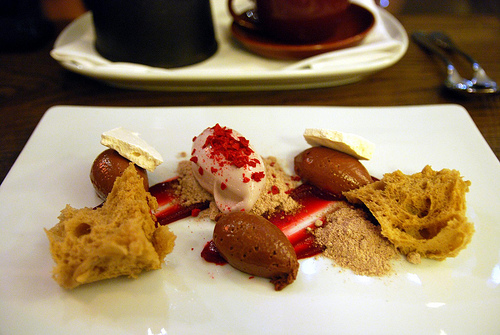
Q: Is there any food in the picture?
A: Yes, there is food.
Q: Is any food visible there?
A: Yes, there is food.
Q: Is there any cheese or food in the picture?
A: Yes, there is food.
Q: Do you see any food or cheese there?
A: Yes, there is food.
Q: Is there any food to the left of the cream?
A: Yes, there is food to the left of the cream.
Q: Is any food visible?
A: Yes, there is food.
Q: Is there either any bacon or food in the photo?
A: Yes, there is food.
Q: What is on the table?
A: The silverware is on the table.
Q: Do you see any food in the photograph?
A: Yes, there is food.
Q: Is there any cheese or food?
A: Yes, there is food.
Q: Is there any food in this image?
A: Yes, there is food.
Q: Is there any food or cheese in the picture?
A: Yes, there is food.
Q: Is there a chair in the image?
A: No, there are no chairs.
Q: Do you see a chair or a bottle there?
A: No, there are no chairs or bottles.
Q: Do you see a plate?
A: Yes, there is a plate.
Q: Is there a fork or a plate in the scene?
A: Yes, there is a plate.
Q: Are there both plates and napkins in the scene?
A: Yes, there are both a plate and a napkin.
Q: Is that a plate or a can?
A: That is a plate.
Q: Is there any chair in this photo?
A: No, there are no chairs.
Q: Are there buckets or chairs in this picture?
A: No, there are no chairs or buckets.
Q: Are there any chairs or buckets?
A: No, there are no chairs or buckets.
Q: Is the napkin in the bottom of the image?
A: No, the napkin is in the top of the image.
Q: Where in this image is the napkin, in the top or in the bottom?
A: The napkin is in the top of the image.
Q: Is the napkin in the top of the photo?
A: Yes, the napkin is in the top of the image.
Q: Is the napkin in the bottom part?
A: No, the napkin is in the top of the image.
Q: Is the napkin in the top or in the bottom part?
A: The napkin is in the top of the image.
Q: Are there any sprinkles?
A: Yes, there are sprinkles.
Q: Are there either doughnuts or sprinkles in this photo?
A: Yes, there are sprinkles.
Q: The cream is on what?
A: The cream is on the plate.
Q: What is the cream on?
A: The cream is on the plate.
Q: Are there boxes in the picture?
A: No, there are no boxes.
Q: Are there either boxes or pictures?
A: No, there are no boxes or pictures.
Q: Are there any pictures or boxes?
A: No, there are no boxes or pictures.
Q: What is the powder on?
A: The powder is on the plate.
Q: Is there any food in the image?
A: Yes, there is food.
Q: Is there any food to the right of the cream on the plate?
A: Yes, there is food to the right of the cream.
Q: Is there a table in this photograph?
A: Yes, there is a table.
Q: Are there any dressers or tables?
A: Yes, there is a table.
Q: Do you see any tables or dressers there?
A: Yes, there is a table.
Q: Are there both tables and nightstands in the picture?
A: No, there is a table but no nightstands.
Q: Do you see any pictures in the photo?
A: No, there are no pictures.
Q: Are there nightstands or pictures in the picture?
A: No, there are no pictures or nightstands.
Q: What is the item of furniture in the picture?
A: The piece of furniture is a table.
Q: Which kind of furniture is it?
A: The piece of furniture is a table.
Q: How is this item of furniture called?
A: This is a table.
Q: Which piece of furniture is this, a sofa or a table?
A: This is a table.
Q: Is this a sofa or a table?
A: This is a table.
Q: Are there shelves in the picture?
A: No, there are no shelves.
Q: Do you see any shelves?
A: No, there are no shelves.